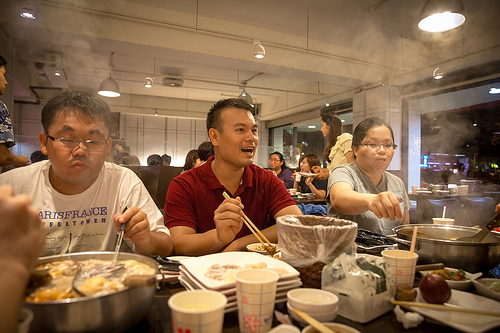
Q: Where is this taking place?
A: A restaurant.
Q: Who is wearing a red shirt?
A: A man.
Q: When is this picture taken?
A: During a meal.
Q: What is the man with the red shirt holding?
A: Chopsticks.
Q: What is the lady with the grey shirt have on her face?
A: Seeing glasses.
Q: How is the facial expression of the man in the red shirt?
A: Laughing.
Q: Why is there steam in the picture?
A: From hot food.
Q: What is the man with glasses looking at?
A: At a bowl of hot food.